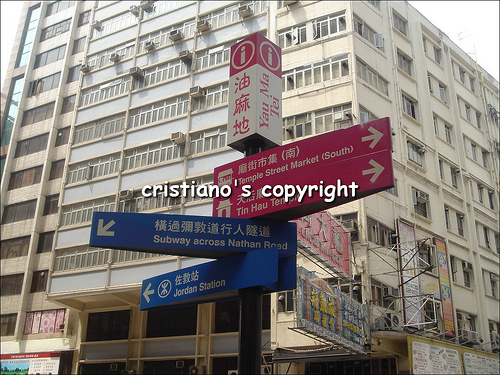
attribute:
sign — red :
[225, 32, 282, 152]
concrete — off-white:
[2, 154, 48, 281]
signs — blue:
[87, 206, 302, 313]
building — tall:
[9, 2, 498, 353]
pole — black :
[239, 287, 265, 373]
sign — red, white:
[230, 33, 285, 145]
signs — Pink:
[207, 117, 401, 220]